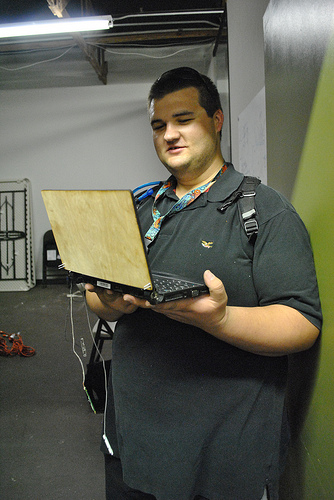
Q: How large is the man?
A: Very big.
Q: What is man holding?
A: Computer.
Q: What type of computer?
A: Laptop.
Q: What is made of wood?
A: Back of laptop.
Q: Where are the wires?
A: In ceiling.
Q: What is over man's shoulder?
A: Strap.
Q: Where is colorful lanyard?
A: Around man's neck.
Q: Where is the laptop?
A: In man's hands.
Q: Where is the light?
A: Above in ceiling.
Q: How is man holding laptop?
A: Both hands.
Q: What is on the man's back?
A: Black bag.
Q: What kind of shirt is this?
A: Black short sleeve shirt.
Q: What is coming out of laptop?
A: White wires.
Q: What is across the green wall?
A: Black shadow.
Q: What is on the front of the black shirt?
A: Bird logo.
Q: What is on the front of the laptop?
A: Brown paper sheet.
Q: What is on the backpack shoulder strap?
A: Buckle.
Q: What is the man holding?
A: A laptop.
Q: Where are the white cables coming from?
A: The laptop.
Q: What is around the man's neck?
A: A lanyard.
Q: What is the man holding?
A: Computer.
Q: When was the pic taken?
A: At night.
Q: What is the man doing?
A: Smiling.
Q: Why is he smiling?
A: He is happy.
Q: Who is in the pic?
A: The man.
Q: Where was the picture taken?
A: At an office.